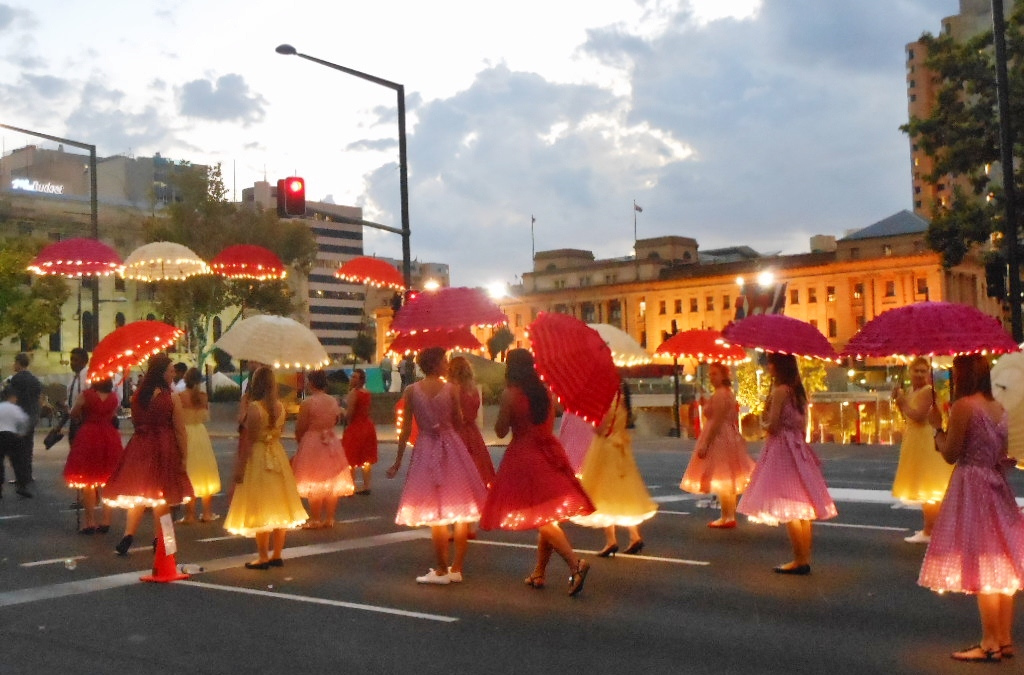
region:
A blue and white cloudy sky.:
[1, 2, 950, 260]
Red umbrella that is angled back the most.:
[528, 307, 618, 428]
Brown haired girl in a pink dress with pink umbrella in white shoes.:
[384, 346, 489, 582]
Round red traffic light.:
[285, 178, 304, 197]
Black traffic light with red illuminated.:
[278, 175, 307, 220]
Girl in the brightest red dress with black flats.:
[340, 365, 378, 499]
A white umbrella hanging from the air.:
[120, 242, 213, 282]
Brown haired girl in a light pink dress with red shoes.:
[678, 361, 756, 530]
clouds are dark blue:
[386, 21, 944, 233]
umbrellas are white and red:
[27, 228, 983, 380]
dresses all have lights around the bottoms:
[64, 413, 1013, 609]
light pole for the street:
[263, 37, 425, 433]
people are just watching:
[1, 340, 88, 486]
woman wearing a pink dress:
[722, 345, 839, 564]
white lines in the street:
[11, 453, 1017, 647]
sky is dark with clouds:
[1, 10, 1020, 268]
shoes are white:
[408, 567, 462, 588]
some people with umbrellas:
[35, 229, 1022, 664]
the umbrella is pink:
[716, 315, 838, 366]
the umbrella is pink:
[844, 303, 1018, 357]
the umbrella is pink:
[529, 302, 616, 424]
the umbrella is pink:
[399, 286, 508, 329]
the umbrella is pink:
[210, 243, 286, 283]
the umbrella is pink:
[333, 255, 404, 293]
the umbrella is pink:
[83, 317, 178, 378]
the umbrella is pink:
[24, 240, 122, 276]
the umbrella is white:
[216, 311, 328, 372]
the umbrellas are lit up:
[29, 239, 1022, 389]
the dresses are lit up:
[78, 379, 1015, 599]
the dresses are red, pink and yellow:
[63, 357, 1016, 593]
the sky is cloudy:
[0, 15, 937, 244]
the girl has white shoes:
[410, 566, 468, 582]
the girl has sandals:
[518, 553, 594, 585]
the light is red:
[291, 179, 305, 198]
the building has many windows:
[509, 274, 956, 345]